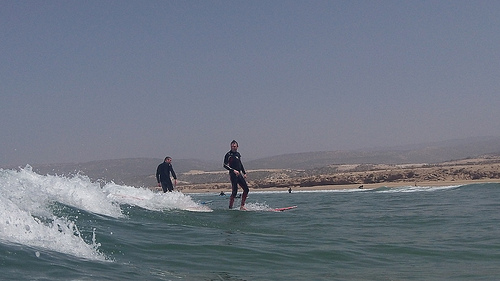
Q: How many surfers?
A: 2.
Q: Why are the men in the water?
A: Surfing.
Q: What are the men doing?
A: Surfing.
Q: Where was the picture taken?
A: Ocean.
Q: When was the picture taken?
A: During the daytime.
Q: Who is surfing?
A: Two men.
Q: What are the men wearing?
A: Wetsuits.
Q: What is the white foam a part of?
A: Wave.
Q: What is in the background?
A: Hills.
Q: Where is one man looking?
A: Back.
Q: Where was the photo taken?
A: Beach.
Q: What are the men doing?
A: Surfboarding?.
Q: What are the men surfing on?
A: Wave.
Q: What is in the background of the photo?
A: Mountain.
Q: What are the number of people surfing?
A: 2.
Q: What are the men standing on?
A: Surfboards.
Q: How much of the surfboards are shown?
A: The tips.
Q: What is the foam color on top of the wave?
A: White.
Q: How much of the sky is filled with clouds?
A: None of it.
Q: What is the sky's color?
A: Light blue.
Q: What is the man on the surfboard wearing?
A: A wetsuit.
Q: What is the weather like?
A: Gloomy.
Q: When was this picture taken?
A: Daytime.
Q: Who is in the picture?
A: Men.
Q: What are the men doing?
A: Surfing.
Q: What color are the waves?
A: White.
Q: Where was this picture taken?
A: A beach.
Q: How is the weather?
A: Clear.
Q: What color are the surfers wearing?
A: Black.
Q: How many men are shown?
A: Two.